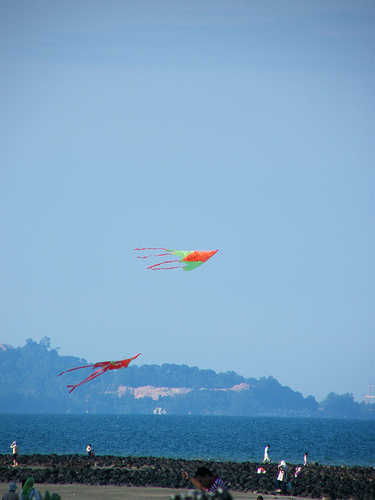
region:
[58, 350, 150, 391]
a red kite in the sky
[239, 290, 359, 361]
a clear blue sky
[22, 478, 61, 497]
a woman in a green hijab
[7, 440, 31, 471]
a man in a white shirt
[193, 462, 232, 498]
a man in a stripped shirt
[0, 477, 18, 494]
a green hat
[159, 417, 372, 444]
a blue ocean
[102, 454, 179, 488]
a rocky beach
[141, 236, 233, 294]
a green and red kite in the sky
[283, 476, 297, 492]
a blue object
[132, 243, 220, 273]
kite is green and orange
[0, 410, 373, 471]
water is blue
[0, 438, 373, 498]
people standing on rocky shore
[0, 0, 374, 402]
kites flying in blue sky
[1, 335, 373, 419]
hills behind water covered in trees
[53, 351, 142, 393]
kite is red and green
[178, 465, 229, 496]
man wearing red and white striped shirt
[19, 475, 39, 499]
woman wearing green scarf on her head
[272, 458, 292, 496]
woman wearing white scarf on her head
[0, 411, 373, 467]
water is choppy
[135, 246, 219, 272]
a yellow and orange kite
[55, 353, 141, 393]
a red kite in the air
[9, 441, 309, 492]
people standing on the rocks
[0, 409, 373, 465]
water in front of the people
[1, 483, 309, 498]
sand in front of the rocks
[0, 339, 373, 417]
trees behind water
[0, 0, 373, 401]
a hazy sky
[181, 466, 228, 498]
a man holding a kite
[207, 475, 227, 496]
a red and white striped shirt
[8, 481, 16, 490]
a blue hat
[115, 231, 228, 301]
this is a kite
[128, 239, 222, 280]
the kite is on air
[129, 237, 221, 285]
the kite is red and green in color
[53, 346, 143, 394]
the kite is red in color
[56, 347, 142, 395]
the kite is wavy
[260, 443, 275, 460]
this is a man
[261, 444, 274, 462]
the man is walking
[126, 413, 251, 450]
the water is blue in color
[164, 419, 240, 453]
the waves are small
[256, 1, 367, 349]
the sky is blue in color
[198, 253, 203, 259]
orange part of a kite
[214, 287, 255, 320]
section of blue sky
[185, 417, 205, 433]
part of a sea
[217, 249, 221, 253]
tip of a kite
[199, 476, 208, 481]
head of a man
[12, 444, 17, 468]
an old man on the shore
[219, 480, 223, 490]
section of a stripped shirt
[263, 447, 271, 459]
a person on the shore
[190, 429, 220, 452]
ripples of the sea water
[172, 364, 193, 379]
a section of a forest